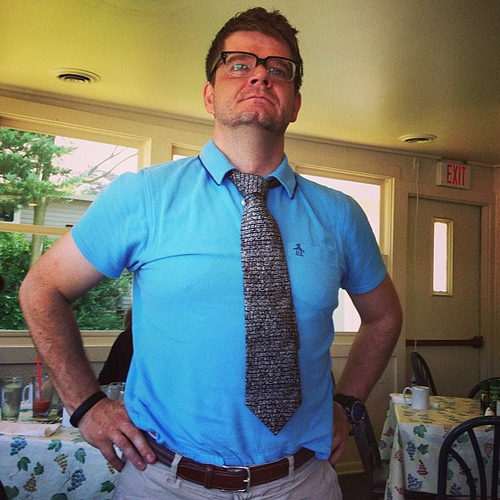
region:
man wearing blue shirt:
[162, 2, 339, 336]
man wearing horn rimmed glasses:
[206, 15, 315, 105]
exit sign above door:
[437, 154, 470, 194]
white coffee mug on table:
[398, 381, 435, 417]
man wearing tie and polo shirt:
[211, 169, 302, 426]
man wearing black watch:
[333, 382, 372, 434]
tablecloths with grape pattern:
[5, 420, 105, 497]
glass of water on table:
[4, 375, 26, 422]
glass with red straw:
[27, 354, 54, 414]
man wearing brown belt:
[142, 428, 335, 490]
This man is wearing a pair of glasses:
[265, 52, 283, 96]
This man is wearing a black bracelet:
[76, 375, 112, 402]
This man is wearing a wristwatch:
[335, 382, 357, 420]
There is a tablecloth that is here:
[412, 413, 423, 461]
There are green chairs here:
[456, 426, 493, 497]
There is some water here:
[5, 382, 25, 408]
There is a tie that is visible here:
[239, 313, 294, 378]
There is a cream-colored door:
[442, 303, 464, 353]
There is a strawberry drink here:
[34, 372, 65, 419]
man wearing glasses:
[210, 22, 321, 97]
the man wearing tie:
[199, 140, 339, 461]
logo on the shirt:
[286, 242, 313, 259]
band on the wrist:
[55, 374, 130, 440]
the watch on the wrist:
[325, 383, 376, 430]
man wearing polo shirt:
[78, 148, 383, 454]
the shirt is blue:
[95, 153, 376, 440]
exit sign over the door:
[431, 158, 472, 186]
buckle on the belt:
[206, 458, 273, 495]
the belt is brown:
[144, 438, 338, 497]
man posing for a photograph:
[15, 6, 481, 477]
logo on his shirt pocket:
[285, 236, 305, 261]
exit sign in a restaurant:
[430, 150, 475, 191]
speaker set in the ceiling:
[42, 60, 99, 90]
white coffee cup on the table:
[400, 380, 433, 410]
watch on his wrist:
[330, 385, 365, 425]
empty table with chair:
[370, 350, 495, 496]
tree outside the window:
[0, 127, 57, 227]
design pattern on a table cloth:
[5, 433, 81, 493]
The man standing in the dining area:
[8, 3, 411, 493]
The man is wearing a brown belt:
[131, 435, 318, 493]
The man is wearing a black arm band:
[63, 382, 113, 430]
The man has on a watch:
[329, 385, 370, 430]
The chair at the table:
[430, 401, 497, 496]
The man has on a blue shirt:
[64, 140, 388, 477]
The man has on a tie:
[225, 163, 309, 439]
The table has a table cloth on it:
[376, 385, 496, 497]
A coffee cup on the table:
[397, 380, 434, 414]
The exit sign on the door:
[431, 156, 476, 191]